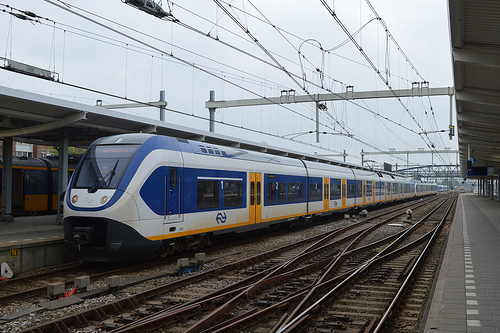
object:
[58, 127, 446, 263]
train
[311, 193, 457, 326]
track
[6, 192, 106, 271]
platform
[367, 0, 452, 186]
wires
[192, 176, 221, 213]
windows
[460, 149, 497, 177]
sign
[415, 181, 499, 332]
platform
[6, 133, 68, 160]
building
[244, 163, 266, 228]
door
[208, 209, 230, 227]
logo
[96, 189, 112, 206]
lights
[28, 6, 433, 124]
sky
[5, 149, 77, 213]
train